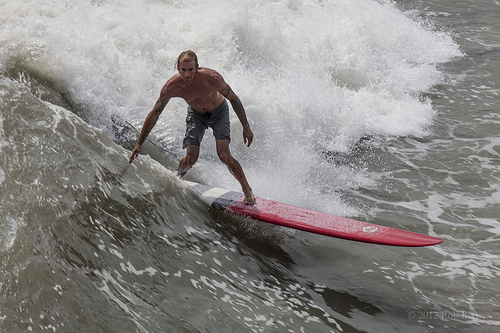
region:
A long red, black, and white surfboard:
[168, 168, 443, 252]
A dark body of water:
[11, 215, 218, 330]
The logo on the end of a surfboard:
[358, 220, 383, 236]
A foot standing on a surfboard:
[236, 185, 266, 207]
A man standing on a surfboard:
[129, 50, 418, 252]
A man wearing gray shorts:
[130, 50, 267, 210]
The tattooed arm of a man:
[218, 78, 261, 148]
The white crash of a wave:
[243, 0, 425, 165]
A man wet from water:
[131, 49, 261, 199]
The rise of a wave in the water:
[12, 151, 232, 323]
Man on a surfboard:
[105, 40, 455, 290]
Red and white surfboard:
[146, 150, 477, 255]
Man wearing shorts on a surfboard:
[115, 26, 295, 241]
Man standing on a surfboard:
[107, 33, 278, 225]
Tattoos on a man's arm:
[215, 74, 257, 146]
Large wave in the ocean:
[33, 18, 466, 250]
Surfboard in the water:
[118, 112, 236, 246]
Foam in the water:
[84, 224, 336, 331]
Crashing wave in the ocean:
[45, 6, 497, 209]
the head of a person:
[173, 48, 202, 85]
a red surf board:
[271, 195, 441, 258]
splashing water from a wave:
[273, 67, 361, 119]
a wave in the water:
[98, 223, 248, 303]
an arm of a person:
[228, 78, 249, 124]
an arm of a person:
[143, 97, 171, 135]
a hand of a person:
[125, 141, 144, 166]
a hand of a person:
[239, 126, 258, 149]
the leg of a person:
[216, 150, 249, 188]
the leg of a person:
[175, 149, 201, 178]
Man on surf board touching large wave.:
[128, 40, 278, 215]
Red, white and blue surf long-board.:
[180, 171, 460, 251]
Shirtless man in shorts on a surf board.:
[132, 45, 277, 212]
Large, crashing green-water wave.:
[16, 30, 486, 300]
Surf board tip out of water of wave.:
[170, 160, 450, 270]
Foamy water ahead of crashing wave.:
[270, 32, 495, 197]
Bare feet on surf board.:
[160, 145, 440, 250]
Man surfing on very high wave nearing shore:
[4, 36, 312, 330]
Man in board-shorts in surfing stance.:
[120, 47, 275, 223]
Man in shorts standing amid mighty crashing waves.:
[9, 1, 454, 181]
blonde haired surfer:
[117, 22, 439, 257]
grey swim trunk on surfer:
[173, 91, 242, 156]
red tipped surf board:
[207, 175, 456, 292]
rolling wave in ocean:
[19, 11, 421, 292]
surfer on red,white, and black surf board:
[107, 18, 441, 272]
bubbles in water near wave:
[78, 168, 288, 310]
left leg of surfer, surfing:
[205, 103, 265, 218]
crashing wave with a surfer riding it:
[112, 22, 417, 206]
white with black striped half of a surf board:
[149, 140, 246, 237]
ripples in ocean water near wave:
[32, 132, 187, 306]